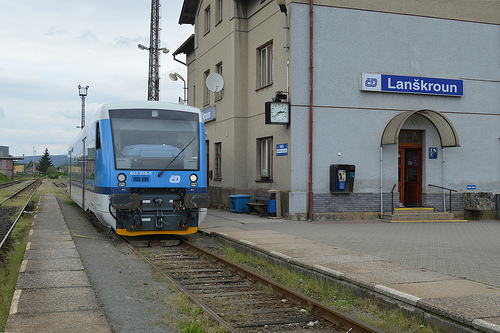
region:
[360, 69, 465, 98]
blue sign on a wall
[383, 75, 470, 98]
white writing on sign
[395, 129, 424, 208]
red door to building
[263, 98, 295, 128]
clock on side of wall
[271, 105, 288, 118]
white face of clock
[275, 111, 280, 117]
long hand of clock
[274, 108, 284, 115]
short hand of clock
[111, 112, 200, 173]
front window of train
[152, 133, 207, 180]
window wiper on train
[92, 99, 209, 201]
blue and white front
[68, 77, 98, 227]
street lamp next to a train car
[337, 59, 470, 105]
sign on the side of a building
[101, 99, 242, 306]
front of a train car on tracks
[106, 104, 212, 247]
front of a train car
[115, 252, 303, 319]
grass growing on train tracks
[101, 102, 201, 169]
windshield on a train car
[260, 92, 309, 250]
clock on the side of a building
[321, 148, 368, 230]
payhone on the side of a building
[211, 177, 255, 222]
blue trashcan next to a wall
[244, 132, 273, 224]
wooden bench near a window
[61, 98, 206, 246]
blue train on a railroad track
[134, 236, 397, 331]
rail road track the blue train ios on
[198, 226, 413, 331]
grass growing between the curb and the rail road track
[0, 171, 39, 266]
rail road track to the left of the train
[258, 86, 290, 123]
clock on building wall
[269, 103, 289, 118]
square face of the clock on the wall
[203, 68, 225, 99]
white satellite dish on the side of the building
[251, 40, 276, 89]
window of the building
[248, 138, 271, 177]
window of the building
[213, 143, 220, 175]
window of the building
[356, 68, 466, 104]
Long rectangular blue sign with white writing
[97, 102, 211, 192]
Blue and white front of a train car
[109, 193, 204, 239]
Dark green and yellow lower part of a train car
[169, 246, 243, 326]
Rusted metal train tracks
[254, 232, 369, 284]
Large multi colored metal panels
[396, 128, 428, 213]
Dark red colored door of a building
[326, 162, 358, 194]
Payphone with a dark metal hood protecting it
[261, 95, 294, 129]
Black clock with a white face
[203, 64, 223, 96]
Large white round satellite dish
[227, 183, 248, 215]
Small blue colored garbage can near a building